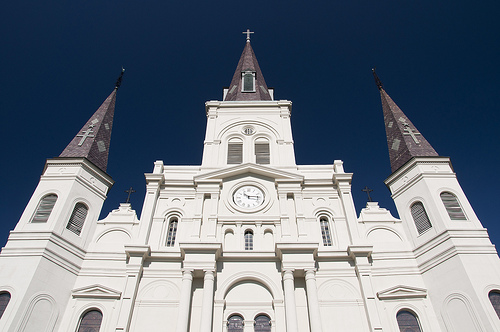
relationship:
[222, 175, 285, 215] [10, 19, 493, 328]
clock on face of building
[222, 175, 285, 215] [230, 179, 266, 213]
clock of clock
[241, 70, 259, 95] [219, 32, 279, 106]
window on top of steeple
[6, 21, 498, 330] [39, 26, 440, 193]
church with steeples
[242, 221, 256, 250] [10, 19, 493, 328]
window on building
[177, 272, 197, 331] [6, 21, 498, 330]
pillar on front of church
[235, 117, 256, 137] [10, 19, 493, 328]
vent on top of building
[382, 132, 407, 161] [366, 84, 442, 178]
diamond shape on side of steeple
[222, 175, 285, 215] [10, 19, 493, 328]
clock on a building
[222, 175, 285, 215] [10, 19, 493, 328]
clock on front of a building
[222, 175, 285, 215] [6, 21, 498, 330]
clock on front of a church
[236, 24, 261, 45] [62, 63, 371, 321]
cross on church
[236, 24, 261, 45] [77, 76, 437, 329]
cross on church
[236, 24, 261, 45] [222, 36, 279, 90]
cross on steeple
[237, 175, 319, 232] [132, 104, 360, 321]
clock on building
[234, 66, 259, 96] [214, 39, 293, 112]
window on steeple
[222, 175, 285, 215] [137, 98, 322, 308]
clock on building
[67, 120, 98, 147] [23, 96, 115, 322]
cross on tower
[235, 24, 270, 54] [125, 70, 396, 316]
cross on church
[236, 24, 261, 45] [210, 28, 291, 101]
cross at top of tower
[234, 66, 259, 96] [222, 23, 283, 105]
window in spire